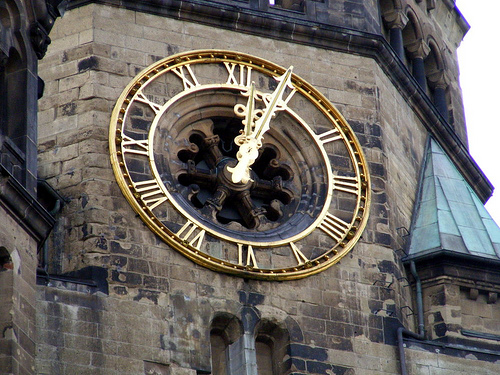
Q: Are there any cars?
A: No, there are no cars.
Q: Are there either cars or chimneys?
A: No, there are no cars or chimneys.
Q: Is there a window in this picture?
A: Yes, there is a window.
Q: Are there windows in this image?
A: Yes, there is a window.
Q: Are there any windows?
A: Yes, there is a window.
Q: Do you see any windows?
A: Yes, there is a window.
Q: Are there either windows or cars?
A: Yes, there is a window.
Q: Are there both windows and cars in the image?
A: No, there is a window but no cars.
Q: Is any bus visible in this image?
A: No, there are no buses.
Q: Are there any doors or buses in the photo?
A: No, there are no buses or doors.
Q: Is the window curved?
A: Yes, the window is curved.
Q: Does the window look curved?
A: Yes, the window is curved.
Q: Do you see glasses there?
A: No, there are no glasses.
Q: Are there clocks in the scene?
A: Yes, there is a clock.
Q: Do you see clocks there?
A: Yes, there is a clock.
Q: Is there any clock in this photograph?
A: Yes, there is a clock.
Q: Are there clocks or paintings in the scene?
A: Yes, there is a clock.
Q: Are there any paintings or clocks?
A: Yes, there is a clock.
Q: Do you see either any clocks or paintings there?
A: Yes, there is a clock.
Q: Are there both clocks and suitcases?
A: No, there is a clock but no suitcases.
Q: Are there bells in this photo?
A: No, there are no bells.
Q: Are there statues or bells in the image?
A: No, there are no bells or statues.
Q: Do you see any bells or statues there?
A: No, there are no bells or statues.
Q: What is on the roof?
A: The clock is on the roof.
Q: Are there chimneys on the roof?
A: No, there is a clock on the roof.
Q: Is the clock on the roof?
A: Yes, the clock is on the roof.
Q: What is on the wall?
A: The clock is on the wall.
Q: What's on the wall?
A: The clock is on the wall.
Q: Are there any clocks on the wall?
A: Yes, there is a clock on the wall.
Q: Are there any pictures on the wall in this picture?
A: No, there is a clock on the wall.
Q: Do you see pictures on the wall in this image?
A: No, there is a clock on the wall.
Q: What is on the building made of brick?
A: The clock is on the building.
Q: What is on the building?
A: The clock is on the building.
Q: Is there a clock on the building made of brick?
A: Yes, there is a clock on the building.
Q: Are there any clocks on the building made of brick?
A: Yes, there is a clock on the building.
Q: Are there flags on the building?
A: No, there is a clock on the building.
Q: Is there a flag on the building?
A: No, there is a clock on the building.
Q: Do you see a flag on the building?
A: No, there is a clock on the building.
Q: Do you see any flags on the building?
A: No, there is a clock on the building.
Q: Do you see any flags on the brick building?
A: No, there is a clock on the building.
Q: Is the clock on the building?
A: Yes, the clock is on the building.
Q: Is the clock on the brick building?
A: Yes, the clock is on the building.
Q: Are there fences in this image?
A: No, there are no fences.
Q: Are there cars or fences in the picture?
A: No, there are no fences or cars.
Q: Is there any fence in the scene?
A: No, there are no fences.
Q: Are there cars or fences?
A: No, there are no fences or cars.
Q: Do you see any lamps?
A: No, there are no lamps.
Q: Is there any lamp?
A: No, there are no lamps.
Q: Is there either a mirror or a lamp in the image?
A: No, there are no lamps or mirrors.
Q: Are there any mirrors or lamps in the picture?
A: No, there are no lamps or mirrors.